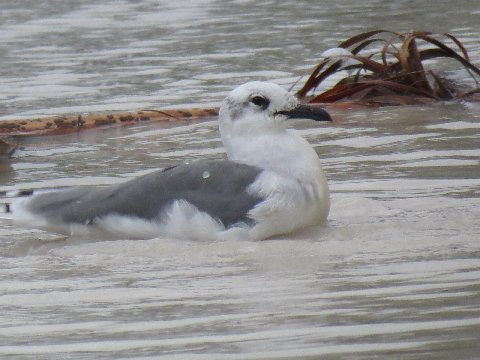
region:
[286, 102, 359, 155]
Bird has black beak.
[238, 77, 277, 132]
Bird has black eye.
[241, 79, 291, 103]
Bird has white head.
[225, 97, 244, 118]
Gray markings on side of bird's head.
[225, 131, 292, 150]
Bird has white neck.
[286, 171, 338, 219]
Bird has white chest.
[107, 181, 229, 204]
Bird has gray wing.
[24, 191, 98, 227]
Bird has gray tail feathers.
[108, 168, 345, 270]
Bird is sitting in water.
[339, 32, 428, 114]
Brown plant sticking out of water.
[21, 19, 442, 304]
a duck on the water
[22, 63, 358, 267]
the duck is white and gray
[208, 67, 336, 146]
the duck's beak is black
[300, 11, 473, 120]
some kind of twig in the water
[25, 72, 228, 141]
a twig in the water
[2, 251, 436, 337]
the water is wavey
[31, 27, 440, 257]
this water is agitated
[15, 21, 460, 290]
this water looks frosty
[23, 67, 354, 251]
the duck is floating on the water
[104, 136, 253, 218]
water on the duck's back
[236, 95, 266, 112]
Bird has dark eye.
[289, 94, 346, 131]
Bird has black beak.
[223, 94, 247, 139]
Gray markings on bird's cheek.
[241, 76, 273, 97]
Bird has white head.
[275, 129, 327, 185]
Bird has white chest.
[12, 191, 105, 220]
Bird has gray and white tail feathers.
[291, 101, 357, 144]
Bird has long beak.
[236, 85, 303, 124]
eye of the duck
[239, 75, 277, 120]
eye of the bird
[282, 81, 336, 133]
nose of the animal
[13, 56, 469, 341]
a duck in water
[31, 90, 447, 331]
a duck walking in water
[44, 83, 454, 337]
a duck running in water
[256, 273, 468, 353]
riddles in the water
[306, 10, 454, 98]
a small tree in water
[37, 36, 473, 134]
a tree fallen down in water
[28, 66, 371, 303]
a bird walking near tree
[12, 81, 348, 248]
white seagull head and beak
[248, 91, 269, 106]
black eye of seagull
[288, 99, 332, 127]
black beak of seagull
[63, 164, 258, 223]
grey wing of seagull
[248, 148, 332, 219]
white body of seagull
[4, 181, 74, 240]
grey and white tail feathers of sea gull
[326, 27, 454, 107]
plants floating in water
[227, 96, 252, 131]
brown fur on saegull face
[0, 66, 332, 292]
seagull floating in water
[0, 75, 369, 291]
seagull swimming in water